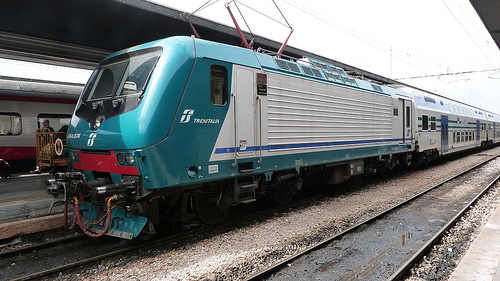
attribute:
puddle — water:
[351, 213, 451, 267]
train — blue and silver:
[40, 34, 497, 182]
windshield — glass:
[74, 61, 221, 129]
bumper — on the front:
[40, 167, 158, 219]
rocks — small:
[60, 143, 499, 279]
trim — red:
[57, 138, 145, 184]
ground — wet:
[0, 145, 498, 277]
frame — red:
[219, 0, 253, 51]